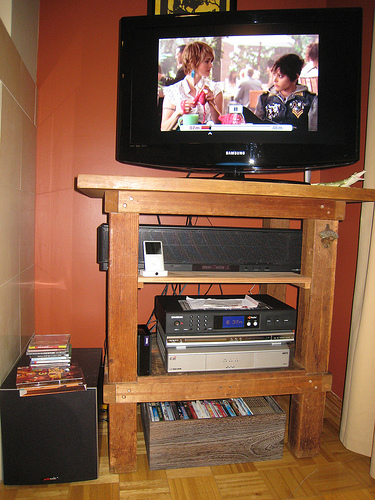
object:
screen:
[148, 32, 322, 141]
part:
[257, 26, 330, 138]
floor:
[232, 467, 352, 497]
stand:
[73, 173, 374, 475]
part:
[276, 176, 350, 456]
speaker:
[0, 336, 99, 486]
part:
[8, 394, 90, 481]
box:
[143, 405, 286, 470]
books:
[148, 402, 155, 421]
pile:
[10, 367, 87, 396]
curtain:
[337, 44, 374, 478]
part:
[337, 204, 373, 486]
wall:
[0, 10, 35, 330]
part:
[269, 462, 371, 499]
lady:
[163, 44, 231, 128]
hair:
[177, 41, 211, 66]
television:
[114, 11, 370, 180]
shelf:
[133, 271, 305, 286]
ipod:
[140, 240, 167, 280]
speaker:
[97, 221, 303, 274]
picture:
[148, 0, 235, 13]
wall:
[37, 15, 115, 173]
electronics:
[95, 223, 302, 282]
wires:
[195, 282, 200, 296]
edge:
[113, 9, 372, 27]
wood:
[101, 371, 333, 406]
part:
[233, 417, 282, 463]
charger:
[140, 264, 169, 278]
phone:
[142, 241, 163, 270]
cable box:
[153, 295, 300, 337]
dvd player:
[165, 345, 290, 375]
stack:
[27, 334, 71, 366]